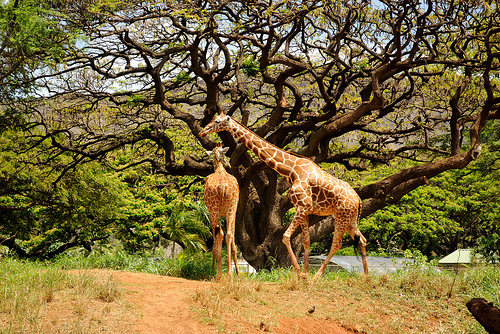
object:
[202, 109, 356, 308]
giraffes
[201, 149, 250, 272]
giraffe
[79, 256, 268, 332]
path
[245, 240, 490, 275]
fence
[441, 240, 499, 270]
buildings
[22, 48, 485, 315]
enclosure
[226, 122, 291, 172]
neck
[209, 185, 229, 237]
tail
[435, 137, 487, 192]
wound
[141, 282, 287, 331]
dirt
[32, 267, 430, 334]
ground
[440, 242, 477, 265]
roof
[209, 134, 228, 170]
head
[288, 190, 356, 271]
legs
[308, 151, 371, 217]
backs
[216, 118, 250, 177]
necks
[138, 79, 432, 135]
mountains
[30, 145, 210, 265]
tree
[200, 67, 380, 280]
giraffe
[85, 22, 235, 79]
sky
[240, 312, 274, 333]
spot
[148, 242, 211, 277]
grass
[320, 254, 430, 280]
house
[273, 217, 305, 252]
knee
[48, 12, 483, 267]
tree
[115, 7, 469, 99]
branches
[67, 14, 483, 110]
lot